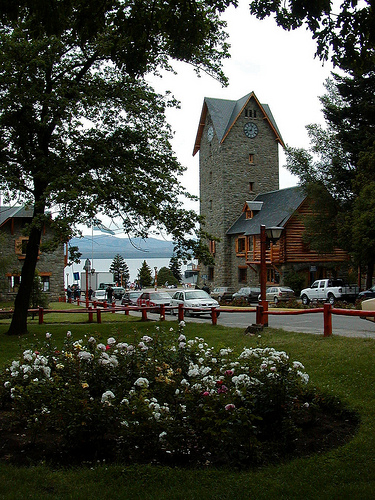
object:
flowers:
[9, 367, 21, 379]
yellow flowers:
[80, 380, 91, 391]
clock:
[244, 122, 258, 139]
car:
[170, 289, 221, 318]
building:
[0, 204, 65, 305]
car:
[137, 289, 172, 314]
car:
[121, 291, 143, 306]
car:
[93, 290, 107, 302]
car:
[258, 285, 295, 305]